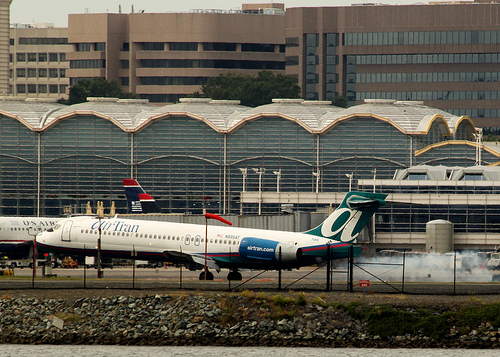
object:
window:
[347, 32, 352, 46]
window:
[355, 74, 362, 82]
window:
[389, 91, 397, 100]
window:
[400, 32, 408, 47]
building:
[284, 4, 499, 140]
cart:
[0, 244, 48, 269]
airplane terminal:
[304, 190, 389, 243]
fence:
[0, 243, 499, 292]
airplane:
[37, 179, 389, 280]